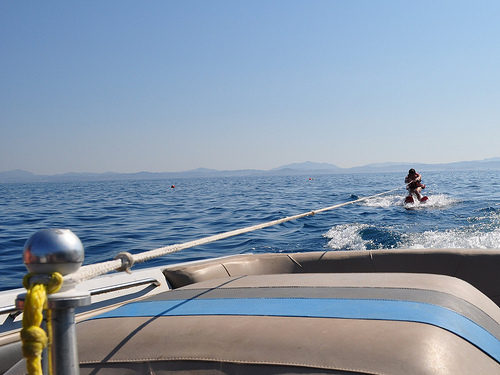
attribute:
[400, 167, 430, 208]
person — waterskiing, crouched, skier, bent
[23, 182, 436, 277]
rope — long, white, tied, ski pull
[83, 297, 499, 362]
strip — blue, leather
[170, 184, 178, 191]
buoy — red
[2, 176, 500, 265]
water — blue, choppy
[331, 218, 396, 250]
wave — behind, small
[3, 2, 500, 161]
sky — clear, blue, white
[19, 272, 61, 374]
rope — hanging, yellow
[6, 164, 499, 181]
mountains — background, horizon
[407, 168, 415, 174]
hair — short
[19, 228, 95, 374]
pole — gray, metal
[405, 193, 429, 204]
skis — red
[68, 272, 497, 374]
covering — leather